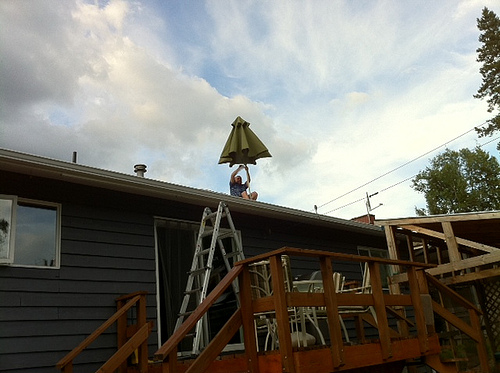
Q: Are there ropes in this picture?
A: No, there are no ropes.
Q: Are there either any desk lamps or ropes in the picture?
A: No, there are no ropes or desk lamps.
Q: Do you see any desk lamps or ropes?
A: No, there are no ropes or desk lamps.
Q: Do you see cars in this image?
A: No, there are no cars.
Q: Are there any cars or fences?
A: No, there are no cars or fences.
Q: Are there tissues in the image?
A: No, there are no tissues.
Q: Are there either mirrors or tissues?
A: No, there are no tissues or mirrors.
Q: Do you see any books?
A: No, there are no books.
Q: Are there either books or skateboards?
A: No, there are no books or skateboards.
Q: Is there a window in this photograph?
A: Yes, there is a window.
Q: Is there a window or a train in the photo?
A: Yes, there is a window.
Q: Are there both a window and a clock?
A: No, there is a window but no clocks.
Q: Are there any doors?
A: Yes, there is a door.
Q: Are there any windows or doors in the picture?
A: Yes, there is a door.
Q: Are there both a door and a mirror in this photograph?
A: No, there is a door but no mirrors.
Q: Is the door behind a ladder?
A: Yes, the door is behind a ladder.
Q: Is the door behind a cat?
A: No, the door is behind a ladder.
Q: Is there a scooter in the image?
A: No, there are no scooters.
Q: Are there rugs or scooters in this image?
A: No, there are no scooters or rugs.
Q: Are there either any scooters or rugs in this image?
A: No, there are no scooters or rugs.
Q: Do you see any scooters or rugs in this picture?
A: No, there are no scooters or rugs.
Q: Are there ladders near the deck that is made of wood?
A: Yes, there is a ladder near the deck.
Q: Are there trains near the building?
A: No, there is a ladder near the building.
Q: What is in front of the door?
A: The ladder is in front of the door.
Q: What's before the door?
A: The ladder is in front of the door.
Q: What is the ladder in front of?
A: The ladder is in front of the door.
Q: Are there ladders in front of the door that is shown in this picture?
A: Yes, there is a ladder in front of the door.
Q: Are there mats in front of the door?
A: No, there is a ladder in front of the door.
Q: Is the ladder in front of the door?
A: Yes, the ladder is in front of the door.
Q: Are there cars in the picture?
A: No, there are no cars.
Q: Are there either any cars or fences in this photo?
A: No, there are no cars or fences.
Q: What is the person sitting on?
A: The person is sitting on the building.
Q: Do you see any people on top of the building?
A: Yes, there is a person on top of the building.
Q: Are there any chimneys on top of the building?
A: No, there is a person on top of the building.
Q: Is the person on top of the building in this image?
A: Yes, the person is on top of the building.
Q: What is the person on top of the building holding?
A: The person is holding the umbrella.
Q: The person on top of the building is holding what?
A: The person is holding the umbrella.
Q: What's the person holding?
A: The person is holding the umbrella.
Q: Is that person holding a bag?
A: No, the person is holding the umbrella.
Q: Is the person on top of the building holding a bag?
A: No, the person is holding the umbrella.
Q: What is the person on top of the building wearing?
A: The person is wearing a shirt.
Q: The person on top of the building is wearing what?
A: The person is wearing a shirt.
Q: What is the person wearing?
A: The person is wearing a shirt.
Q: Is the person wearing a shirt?
A: Yes, the person is wearing a shirt.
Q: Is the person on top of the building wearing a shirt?
A: Yes, the person is wearing a shirt.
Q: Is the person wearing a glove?
A: No, the person is wearing a shirt.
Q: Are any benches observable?
A: No, there are no benches.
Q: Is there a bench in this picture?
A: No, there are no benches.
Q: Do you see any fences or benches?
A: No, there are no benches or fences.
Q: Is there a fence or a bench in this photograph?
A: No, there are no benches or fences.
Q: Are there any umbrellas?
A: Yes, there is an umbrella.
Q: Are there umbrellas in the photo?
A: Yes, there is an umbrella.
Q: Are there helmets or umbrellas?
A: Yes, there is an umbrella.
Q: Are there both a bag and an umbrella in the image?
A: No, there is an umbrella but no bags.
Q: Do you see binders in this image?
A: No, there are no binders.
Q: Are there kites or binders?
A: No, there are no binders or kites.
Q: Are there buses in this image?
A: No, there are no buses.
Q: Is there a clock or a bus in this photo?
A: No, there are no buses or clocks.